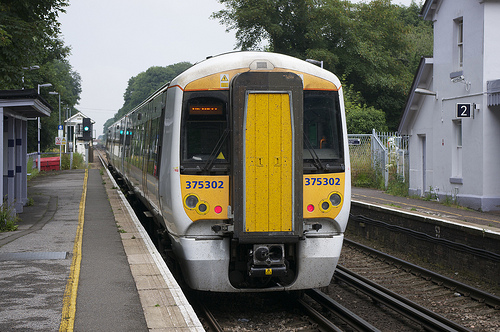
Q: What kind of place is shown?
A: It is a city.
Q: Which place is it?
A: It is a city.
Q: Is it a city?
A: Yes, it is a city.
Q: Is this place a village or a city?
A: It is a city.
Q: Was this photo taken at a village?
A: No, the picture was taken in a city.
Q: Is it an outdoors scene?
A: Yes, it is outdoors.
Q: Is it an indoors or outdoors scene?
A: It is outdoors.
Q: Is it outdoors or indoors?
A: It is outdoors.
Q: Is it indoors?
A: No, it is outdoors.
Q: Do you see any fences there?
A: Yes, there is a fence.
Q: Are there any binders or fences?
A: Yes, there is a fence.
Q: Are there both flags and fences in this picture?
A: No, there is a fence but no flags.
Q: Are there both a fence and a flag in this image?
A: No, there is a fence but no flags.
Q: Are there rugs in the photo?
A: No, there are no rugs.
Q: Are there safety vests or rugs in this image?
A: No, there are no rugs or safety vests.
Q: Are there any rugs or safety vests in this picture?
A: No, there are no rugs or safety vests.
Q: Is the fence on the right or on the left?
A: The fence is on the right of the image.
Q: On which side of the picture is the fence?
A: The fence is on the right of the image.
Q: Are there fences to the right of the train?
A: Yes, there is a fence to the right of the train.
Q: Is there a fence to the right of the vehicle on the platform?
A: Yes, there is a fence to the right of the train.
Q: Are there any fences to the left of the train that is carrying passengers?
A: No, the fence is to the right of the train.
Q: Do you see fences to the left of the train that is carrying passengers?
A: No, the fence is to the right of the train.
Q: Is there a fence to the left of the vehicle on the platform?
A: No, the fence is to the right of the train.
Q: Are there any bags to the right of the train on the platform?
A: No, there is a fence to the right of the train.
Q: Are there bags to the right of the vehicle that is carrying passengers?
A: No, there is a fence to the right of the train.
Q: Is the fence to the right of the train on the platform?
A: Yes, the fence is to the right of the train.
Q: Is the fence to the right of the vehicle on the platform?
A: Yes, the fence is to the right of the train.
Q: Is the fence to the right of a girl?
A: No, the fence is to the right of the train.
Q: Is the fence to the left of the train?
A: No, the fence is to the right of the train.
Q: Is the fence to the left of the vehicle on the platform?
A: No, the fence is to the right of the train.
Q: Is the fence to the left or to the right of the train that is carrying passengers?
A: The fence is to the right of the train.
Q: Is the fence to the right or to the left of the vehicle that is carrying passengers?
A: The fence is to the right of the train.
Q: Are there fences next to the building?
A: Yes, there is a fence next to the building.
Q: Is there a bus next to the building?
A: No, there is a fence next to the building.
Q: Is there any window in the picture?
A: Yes, there are windows.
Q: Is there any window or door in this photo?
A: Yes, there are windows.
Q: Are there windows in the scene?
A: Yes, there is a window.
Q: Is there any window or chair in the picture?
A: Yes, there is a window.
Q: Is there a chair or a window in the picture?
A: Yes, there is a window.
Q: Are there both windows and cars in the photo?
A: No, there is a window but no cars.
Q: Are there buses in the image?
A: No, there are no buses.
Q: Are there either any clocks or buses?
A: No, there are no buses or clocks.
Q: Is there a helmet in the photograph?
A: No, there are no helmets.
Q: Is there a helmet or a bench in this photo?
A: No, there are no helmets or benches.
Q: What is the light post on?
A: The light post is on the platform.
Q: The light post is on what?
A: The light post is on the platform.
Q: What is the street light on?
A: The light post is on the platform.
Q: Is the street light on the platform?
A: Yes, the street light is on the platform.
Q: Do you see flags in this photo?
A: No, there are no flags.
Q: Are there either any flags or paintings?
A: No, there are no flags or paintings.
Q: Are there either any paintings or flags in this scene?
A: No, there are no flags or paintings.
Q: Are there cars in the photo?
A: No, there are no cars.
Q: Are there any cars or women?
A: No, there are no cars or women.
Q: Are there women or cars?
A: No, there are no cars or women.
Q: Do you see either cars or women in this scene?
A: No, there are no cars or women.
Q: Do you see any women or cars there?
A: No, there are no cars or women.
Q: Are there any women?
A: No, there are no women.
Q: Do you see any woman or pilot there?
A: No, there are no women or pilots.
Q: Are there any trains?
A: Yes, there is a train.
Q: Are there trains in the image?
A: Yes, there is a train.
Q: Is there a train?
A: Yes, there is a train.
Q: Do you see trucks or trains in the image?
A: Yes, there is a train.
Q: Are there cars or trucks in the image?
A: No, there are no cars or trucks.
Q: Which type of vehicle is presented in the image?
A: The vehicle is a train.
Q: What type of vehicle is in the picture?
A: The vehicle is a train.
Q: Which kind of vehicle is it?
A: The vehicle is a train.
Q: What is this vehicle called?
A: This is a train.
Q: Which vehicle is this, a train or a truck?
A: This is a train.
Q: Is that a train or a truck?
A: That is a train.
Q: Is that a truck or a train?
A: That is a train.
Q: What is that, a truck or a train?
A: That is a train.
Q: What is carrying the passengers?
A: The train is carrying the passengers.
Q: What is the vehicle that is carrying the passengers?
A: The vehicle is a train.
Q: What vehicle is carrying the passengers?
A: The vehicle is a train.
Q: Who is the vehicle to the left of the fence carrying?
A: The train is carrying passengers.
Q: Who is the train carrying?
A: The train is carrying passengers.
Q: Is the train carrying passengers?
A: Yes, the train is carrying passengers.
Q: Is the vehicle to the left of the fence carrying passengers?
A: Yes, the train is carrying passengers.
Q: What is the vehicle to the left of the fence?
A: The vehicle is a train.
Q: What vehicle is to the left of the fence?
A: The vehicle is a train.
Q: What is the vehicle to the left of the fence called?
A: The vehicle is a train.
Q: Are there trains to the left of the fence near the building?
A: Yes, there is a train to the left of the fence.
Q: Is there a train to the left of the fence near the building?
A: Yes, there is a train to the left of the fence.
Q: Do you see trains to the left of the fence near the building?
A: Yes, there is a train to the left of the fence.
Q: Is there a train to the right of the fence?
A: No, the train is to the left of the fence.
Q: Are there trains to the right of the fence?
A: No, the train is to the left of the fence.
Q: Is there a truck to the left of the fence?
A: No, there is a train to the left of the fence.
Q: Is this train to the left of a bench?
A: No, the train is to the left of the fence.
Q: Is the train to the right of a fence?
A: No, the train is to the left of a fence.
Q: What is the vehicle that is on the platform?
A: The vehicle is a train.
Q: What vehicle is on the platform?
A: The vehicle is a train.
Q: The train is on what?
A: The train is on the platform.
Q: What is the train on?
A: The train is on the platform.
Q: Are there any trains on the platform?
A: Yes, there is a train on the platform.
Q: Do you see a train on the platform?
A: Yes, there is a train on the platform.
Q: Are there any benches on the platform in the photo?
A: No, there is a train on the platform.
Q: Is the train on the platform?
A: Yes, the train is on the platform.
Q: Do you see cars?
A: No, there are no cars.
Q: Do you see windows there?
A: Yes, there is a window.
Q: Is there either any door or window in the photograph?
A: Yes, there is a window.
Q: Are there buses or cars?
A: No, there are no cars or buses.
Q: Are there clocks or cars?
A: No, there are no cars or clocks.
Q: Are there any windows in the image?
A: Yes, there is a window.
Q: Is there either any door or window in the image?
A: Yes, there is a window.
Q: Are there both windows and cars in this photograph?
A: No, there is a window but no cars.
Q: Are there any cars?
A: No, there are no cars.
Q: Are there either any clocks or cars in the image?
A: No, there are no cars or clocks.